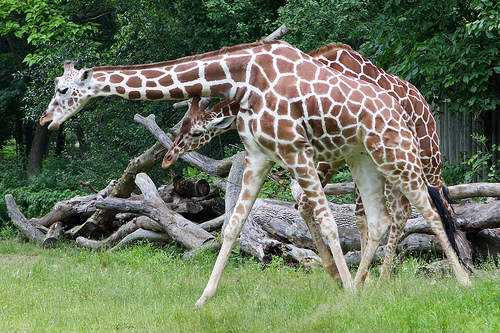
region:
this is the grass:
[31, 254, 91, 318]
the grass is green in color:
[38, 268, 171, 325]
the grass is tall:
[93, 257, 157, 313]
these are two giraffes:
[43, 44, 480, 299]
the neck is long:
[93, 57, 228, 92]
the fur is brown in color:
[278, 75, 343, 122]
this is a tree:
[406, 0, 486, 79]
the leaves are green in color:
[417, 39, 482, 76]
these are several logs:
[56, 193, 203, 234]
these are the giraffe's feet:
[186, 168, 428, 313]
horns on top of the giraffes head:
[47, 52, 94, 92]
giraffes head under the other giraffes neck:
[133, 85, 252, 185]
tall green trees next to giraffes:
[0, 2, 117, 143]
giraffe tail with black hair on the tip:
[398, 135, 475, 270]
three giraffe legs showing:
[215, 143, 360, 328]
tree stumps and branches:
[30, 167, 208, 271]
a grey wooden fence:
[426, 87, 498, 161]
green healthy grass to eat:
[30, 232, 318, 315]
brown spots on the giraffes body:
[224, 35, 351, 124]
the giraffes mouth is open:
[18, 100, 80, 156]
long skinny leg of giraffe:
[197, 145, 268, 309]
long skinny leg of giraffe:
[282, 141, 357, 288]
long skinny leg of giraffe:
[367, 135, 465, 284]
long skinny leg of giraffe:
[344, 147, 390, 285]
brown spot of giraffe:
[277, 117, 294, 142]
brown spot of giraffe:
[256, 53, 276, 79]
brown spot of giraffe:
[347, 101, 359, 115]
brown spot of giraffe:
[297, 61, 319, 79]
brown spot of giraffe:
[142, 69, 165, 76]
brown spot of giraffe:
[177, 65, 204, 81]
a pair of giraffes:
[27, 15, 478, 319]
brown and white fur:
[216, 39, 363, 134]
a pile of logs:
[16, 122, 493, 287]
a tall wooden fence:
[394, 80, 499, 194]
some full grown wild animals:
[31, 45, 488, 317]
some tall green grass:
[34, 207, 482, 331]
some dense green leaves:
[90, 112, 138, 143]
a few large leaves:
[4, 19, 79, 49]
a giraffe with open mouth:
[26, 47, 118, 137]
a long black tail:
[411, 174, 483, 282]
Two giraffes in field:
[43, 52, 479, 307]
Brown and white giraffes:
[38, 32, 472, 291]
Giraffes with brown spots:
[44, 42, 480, 300]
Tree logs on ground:
[10, 125, 249, 254]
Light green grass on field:
[7, 255, 489, 330]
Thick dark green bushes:
[26, 3, 474, 164]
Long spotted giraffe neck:
[97, 50, 257, 102]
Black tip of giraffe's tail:
[431, 189, 467, 250]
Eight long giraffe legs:
[196, 158, 481, 298]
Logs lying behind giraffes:
[201, 148, 498, 255]